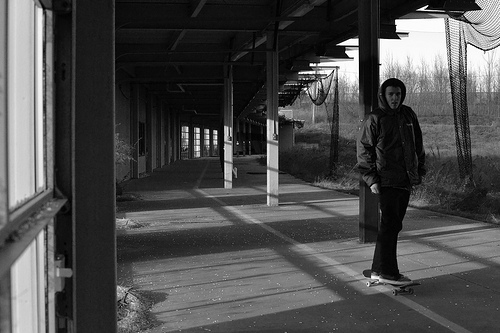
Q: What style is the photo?
A: Black and white.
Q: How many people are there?
A: 1.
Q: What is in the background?
A: Trees.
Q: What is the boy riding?
A: Skateboard.